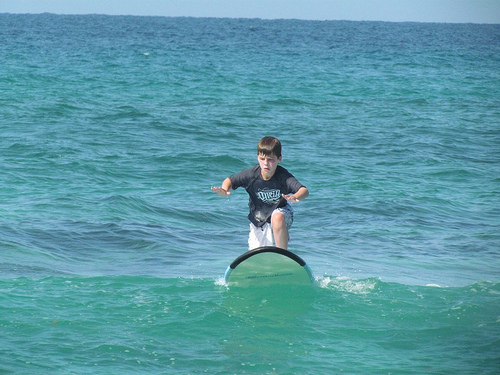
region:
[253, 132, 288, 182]
the head of a boy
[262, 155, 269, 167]
the nose of a boy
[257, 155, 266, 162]
the eye of a boy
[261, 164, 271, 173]
the mouth of a boy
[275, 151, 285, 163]
the ear of a boy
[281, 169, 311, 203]
the arm of a boy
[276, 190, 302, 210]
the hand of a boy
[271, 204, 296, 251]
the leg of a boy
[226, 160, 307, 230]
a gray tee shirt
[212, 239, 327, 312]
a white and black surfboard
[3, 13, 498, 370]
The water is blue.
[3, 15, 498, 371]
The water is wavy.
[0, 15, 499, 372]
The water is ripply.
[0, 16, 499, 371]
The water is engaging.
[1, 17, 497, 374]
The water is zealous.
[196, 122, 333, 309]
Boy is on surfboard.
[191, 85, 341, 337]
The boy is wet.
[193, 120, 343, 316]
Boy is wearing shirt.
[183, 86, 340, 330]
The boy has hair.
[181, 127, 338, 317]
Boy's hair is short.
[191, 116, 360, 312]
little boy surfing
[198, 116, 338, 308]
little boy standing on a surfboard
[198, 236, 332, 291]
top of the board sticking out of the wave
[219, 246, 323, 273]
thick black border on the tip of the board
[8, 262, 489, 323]
very small waves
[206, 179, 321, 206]
hands outstretched in front of the body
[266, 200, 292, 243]
knee bent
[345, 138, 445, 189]
small ripples in the water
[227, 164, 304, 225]
black short sleved shirt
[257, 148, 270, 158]
tufts of hair sticking to the forehead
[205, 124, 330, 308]
a kid on a surfboard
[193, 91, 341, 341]
a kid surfing in the ocean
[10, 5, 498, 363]
a scene in the ocean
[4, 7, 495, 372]
a scene in the day time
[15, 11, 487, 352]
a scene outside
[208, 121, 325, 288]
a kid in a black shirt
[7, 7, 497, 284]
some blue water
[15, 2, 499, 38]
a blue sky with no clouds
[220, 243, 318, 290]
a black, blue, and white surfboard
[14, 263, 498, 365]
a wave being used by the kid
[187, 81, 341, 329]
A boy on a surfboard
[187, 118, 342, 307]
A boy balancing on a surfboard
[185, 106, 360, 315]
A boy on a surfboard in the ocean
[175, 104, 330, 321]
A boy with wet hair on a surfboard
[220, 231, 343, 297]
A surfboard coming out of the water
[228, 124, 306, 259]
A boy wearing white shorts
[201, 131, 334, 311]
A boy wearing wet clothes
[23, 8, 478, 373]
A large body of water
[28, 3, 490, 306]
Small waves in the ocean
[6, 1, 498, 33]
The horizon at the ocean